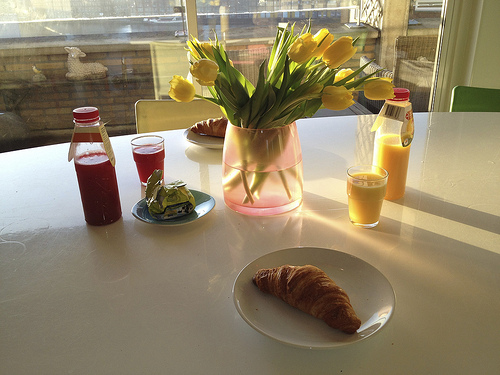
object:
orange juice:
[347, 137, 408, 224]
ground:
[0, 110, 500, 375]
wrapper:
[142, 170, 196, 220]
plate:
[130, 188, 215, 226]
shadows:
[234, 146, 500, 303]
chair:
[449, 85, 498, 111]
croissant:
[251, 265, 362, 335]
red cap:
[73, 107, 99, 120]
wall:
[11, 45, 109, 82]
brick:
[0, 22, 383, 130]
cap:
[394, 88, 410, 99]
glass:
[130, 135, 165, 186]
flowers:
[168, 28, 397, 110]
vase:
[222, 121, 304, 216]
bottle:
[370, 88, 415, 200]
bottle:
[68, 107, 123, 226]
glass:
[346, 165, 389, 229]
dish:
[232, 246, 397, 350]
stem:
[253, 33, 287, 125]